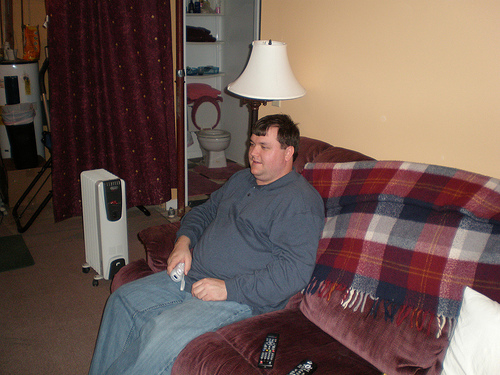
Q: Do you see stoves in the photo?
A: No, there are no stoves.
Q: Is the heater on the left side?
A: Yes, the heater is on the left of the image.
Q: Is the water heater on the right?
A: No, the heater is on the left of the image.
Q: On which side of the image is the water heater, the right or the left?
A: The heater is on the left of the image.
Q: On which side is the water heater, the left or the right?
A: The heater is on the left of the image.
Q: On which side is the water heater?
A: The heater is on the left of the image.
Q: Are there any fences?
A: No, there are no fences.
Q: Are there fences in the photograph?
A: No, there are no fences.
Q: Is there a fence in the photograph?
A: No, there are no fences.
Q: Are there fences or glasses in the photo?
A: No, there are no fences or glasses.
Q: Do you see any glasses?
A: No, there are no glasses.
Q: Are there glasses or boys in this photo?
A: No, there are no glasses or boys.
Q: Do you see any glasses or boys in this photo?
A: No, there are no glasses or boys.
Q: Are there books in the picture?
A: No, there are no books.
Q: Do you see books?
A: No, there are no books.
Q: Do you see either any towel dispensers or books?
A: No, there are no books or towel dispensers.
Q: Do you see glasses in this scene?
A: No, there are no glasses.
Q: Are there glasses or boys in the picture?
A: No, there are no glasses or boys.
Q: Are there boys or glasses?
A: No, there are no glasses or boys.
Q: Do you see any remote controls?
A: Yes, there is a remote control.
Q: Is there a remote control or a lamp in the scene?
A: Yes, there is a remote control.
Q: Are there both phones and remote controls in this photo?
A: No, there is a remote control but no phones.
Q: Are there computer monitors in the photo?
A: No, there are no computer monitors.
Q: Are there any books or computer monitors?
A: No, there are no computer monitors or books.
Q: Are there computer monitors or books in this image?
A: No, there are no computer monitors or books.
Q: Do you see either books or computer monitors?
A: No, there are no computer monitors or books.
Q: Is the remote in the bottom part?
A: Yes, the remote is in the bottom of the image.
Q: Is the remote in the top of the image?
A: No, the remote is in the bottom of the image.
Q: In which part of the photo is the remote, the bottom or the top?
A: The remote is in the bottom of the image.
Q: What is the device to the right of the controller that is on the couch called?
A: The device is a remote control.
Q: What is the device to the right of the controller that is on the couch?
A: The device is a remote control.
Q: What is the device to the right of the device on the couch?
A: The device is a remote control.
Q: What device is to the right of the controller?
A: The device is a remote control.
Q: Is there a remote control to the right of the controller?
A: Yes, there is a remote control to the right of the controller.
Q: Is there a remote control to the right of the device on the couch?
A: Yes, there is a remote control to the right of the controller.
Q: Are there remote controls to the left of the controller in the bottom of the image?
A: No, the remote control is to the right of the controller.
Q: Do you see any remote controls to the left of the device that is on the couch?
A: No, the remote control is to the right of the controller.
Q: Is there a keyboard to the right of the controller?
A: No, there is a remote control to the right of the controller.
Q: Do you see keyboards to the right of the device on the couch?
A: No, there is a remote control to the right of the controller.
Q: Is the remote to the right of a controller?
A: Yes, the remote is to the right of a controller.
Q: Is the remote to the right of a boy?
A: No, the remote is to the right of a controller.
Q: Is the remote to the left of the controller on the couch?
A: No, the remote is to the right of the controller.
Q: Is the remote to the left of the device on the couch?
A: No, the remote is to the right of the controller.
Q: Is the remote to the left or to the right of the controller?
A: The remote is to the right of the controller.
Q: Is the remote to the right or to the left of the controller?
A: The remote is to the right of the controller.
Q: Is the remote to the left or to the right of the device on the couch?
A: The remote is to the right of the controller.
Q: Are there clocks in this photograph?
A: No, there are no clocks.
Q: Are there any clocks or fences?
A: No, there are no clocks or fences.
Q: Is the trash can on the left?
A: Yes, the trash can is on the left of the image.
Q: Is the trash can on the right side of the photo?
A: No, the trash can is on the left of the image.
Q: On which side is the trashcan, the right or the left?
A: The trashcan is on the left of the image.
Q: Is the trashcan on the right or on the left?
A: The trashcan is on the left of the image.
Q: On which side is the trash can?
A: The trash can is on the left of the image.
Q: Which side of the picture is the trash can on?
A: The trash can is on the left of the image.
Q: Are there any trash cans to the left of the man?
A: Yes, there is a trash can to the left of the man.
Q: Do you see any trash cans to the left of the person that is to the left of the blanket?
A: Yes, there is a trash can to the left of the man.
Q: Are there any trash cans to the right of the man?
A: No, the trash can is to the left of the man.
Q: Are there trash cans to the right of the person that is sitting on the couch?
A: No, the trash can is to the left of the man.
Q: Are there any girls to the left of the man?
A: No, there is a trash can to the left of the man.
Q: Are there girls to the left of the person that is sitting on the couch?
A: No, there is a trash can to the left of the man.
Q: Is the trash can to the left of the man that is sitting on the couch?
A: Yes, the trash can is to the left of the man.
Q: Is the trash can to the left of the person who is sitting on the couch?
A: Yes, the trash can is to the left of the man.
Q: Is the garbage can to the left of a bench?
A: No, the garbage can is to the left of the man.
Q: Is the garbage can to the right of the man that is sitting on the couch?
A: No, the garbage can is to the left of the man.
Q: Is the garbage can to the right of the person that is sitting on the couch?
A: No, the garbage can is to the left of the man.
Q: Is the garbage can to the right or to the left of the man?
A: The garbage can is to the left of the man.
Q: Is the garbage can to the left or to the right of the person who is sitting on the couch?
A: The garbage can is to the left of the man.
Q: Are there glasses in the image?
A: No, there are no glasses.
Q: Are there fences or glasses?
A: No, there are no glasses or fences.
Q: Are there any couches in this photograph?
A: Yes, there is a couch.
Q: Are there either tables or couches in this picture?
A: Yes, there is a couch.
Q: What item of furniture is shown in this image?
A: The piece of furniture is a couch.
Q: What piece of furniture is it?
A: The piece of furniture is a couch.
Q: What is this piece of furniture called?
A: This is a couch.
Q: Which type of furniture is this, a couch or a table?
A: This is a couch.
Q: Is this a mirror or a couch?
A: This is a couch.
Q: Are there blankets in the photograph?
A: Yes, there is a blanket.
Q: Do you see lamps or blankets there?
A: Yes, there is a blanket.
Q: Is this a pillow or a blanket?
A: This is a blanket.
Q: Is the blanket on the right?
A: Yes, the blanket is on the right of the image.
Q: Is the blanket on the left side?
A: No, the blanket is on the right of the image.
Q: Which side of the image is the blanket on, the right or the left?
A: The blanket is on the right of the image.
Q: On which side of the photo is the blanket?
A: The blanket is on the right of the image.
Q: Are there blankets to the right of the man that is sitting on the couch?
A: Yes, there is a blanket to the right of the man.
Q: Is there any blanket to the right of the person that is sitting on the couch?
A: Yes, there is a blanket to the right of the man.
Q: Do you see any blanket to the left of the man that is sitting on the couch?
A: No, the blanket is to the right of the man.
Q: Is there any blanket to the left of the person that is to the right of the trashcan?
A: No, the blanket is to the right of the man.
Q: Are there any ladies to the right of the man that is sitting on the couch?
A: No, there is a blanket to the right of the man.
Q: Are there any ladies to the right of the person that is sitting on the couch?
A: No, there is a blanket to the right of the man.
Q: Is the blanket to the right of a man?
A: Yes, the blanket is to the right of a man.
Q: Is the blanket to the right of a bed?
A: No, the blanket is to the right of a man.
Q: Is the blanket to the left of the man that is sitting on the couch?
A: No, the blanket is to the right of the man.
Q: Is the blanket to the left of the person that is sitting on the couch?
A: No, the blanket is to the right of the man.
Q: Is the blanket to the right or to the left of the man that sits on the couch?
A: The blanket is to the right of the man.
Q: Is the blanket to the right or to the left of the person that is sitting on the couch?
A: The blanket is to the right of the man.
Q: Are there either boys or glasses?
A: No, there are no glasses or boys.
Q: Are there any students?
A: No, there are no students.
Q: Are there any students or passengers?
A: No, there are no students or passengers.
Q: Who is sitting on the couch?
A: The man is sitting on the couch.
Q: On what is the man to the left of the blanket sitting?
A: The man is sitting on the couch.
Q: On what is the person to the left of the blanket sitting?
A: The man is sitting on the couch.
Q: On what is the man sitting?
A: The man is sitting on the couch.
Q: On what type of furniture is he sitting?
A: The man is sitting on the couch.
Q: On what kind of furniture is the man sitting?
A: The man is sitting on the couch.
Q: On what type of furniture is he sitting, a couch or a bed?
A: The man is sitting on a couch.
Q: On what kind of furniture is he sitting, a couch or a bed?
A: The man is sitting on a couch.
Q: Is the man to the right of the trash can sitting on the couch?
A: Yes, the man is sitting on the couch.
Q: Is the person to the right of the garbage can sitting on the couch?
A: Yes, the man is sitting on the couch.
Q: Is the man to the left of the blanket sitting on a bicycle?
A: No, the man is sitting on the couch.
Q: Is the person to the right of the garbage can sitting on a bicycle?
A: No, the man is sitting on the couch.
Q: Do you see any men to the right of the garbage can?
A: Yes, there is a man to the right of the garbage can.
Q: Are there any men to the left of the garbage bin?
A: No, the man is to the right of the garbage bin.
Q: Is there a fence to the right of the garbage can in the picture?
A: No, there is a man to the right of the garbage can.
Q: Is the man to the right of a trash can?
A: Yes, the man is to the right of a trash can.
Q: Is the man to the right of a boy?
A: No, the man is to the right of a trash can.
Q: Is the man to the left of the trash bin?
A: No, the man is to the right of the trash bin.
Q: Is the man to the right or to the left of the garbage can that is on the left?
A: The man is to the right of the garbage can.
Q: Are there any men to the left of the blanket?
A: Yes, there is a man to the left of the blanket.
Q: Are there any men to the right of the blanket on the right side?
A: No, the man is to the left of the blanket.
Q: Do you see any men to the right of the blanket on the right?
A: No, the man is to the left of the blanket.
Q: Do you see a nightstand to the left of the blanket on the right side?
A: No, there is a man to the left of the blanket.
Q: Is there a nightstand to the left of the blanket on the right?
A: No, there is a man to the left of the blanket.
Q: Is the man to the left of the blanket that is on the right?
A: Yes, the man is to the left of the blanket.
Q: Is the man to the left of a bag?
A: No, the man is to the left of the blanket.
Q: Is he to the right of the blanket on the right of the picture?
A: No, the man is to the left of the blanket.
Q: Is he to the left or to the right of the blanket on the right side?
A: The man is to the left of the blanket.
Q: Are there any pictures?
A: No, there are no pictures.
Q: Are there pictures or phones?
A: No, there are no pictures or phones.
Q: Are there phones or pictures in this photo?
A: No, there are no pictures or phones.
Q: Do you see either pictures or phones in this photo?
A: No, there are no pictures or phones.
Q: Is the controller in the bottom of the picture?
A: Yes, the controller is in the bottom of the image.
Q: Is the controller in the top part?
A: No, the controller is in the bottom of the image.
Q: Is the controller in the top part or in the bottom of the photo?
A: The controller is in the bottom of the image.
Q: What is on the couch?
A: The controller is on the couch.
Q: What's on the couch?
A: The controller is on the couch.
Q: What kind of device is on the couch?
A: The device is a controller.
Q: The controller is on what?
A: The controller is on the couch.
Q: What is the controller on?
A: The controller is on the couch.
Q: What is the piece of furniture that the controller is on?
A: The piece of furniture is a couch.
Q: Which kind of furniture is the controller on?
A: The controller is on the couch.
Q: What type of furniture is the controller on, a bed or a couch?
A: The controller is on a couch.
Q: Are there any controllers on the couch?
A: Yes, there is a controller on the couch.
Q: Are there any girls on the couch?
A: No, there is a controller on the couch.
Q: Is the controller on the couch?
A: Yes, the controller is on the couch.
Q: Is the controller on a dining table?
A: No, the controller is on the couch.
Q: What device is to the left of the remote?
A: The device is a controller.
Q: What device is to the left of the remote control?
A: The device is a controller.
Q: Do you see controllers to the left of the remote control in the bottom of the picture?
A: Yes, there is a controller to the left of the remote.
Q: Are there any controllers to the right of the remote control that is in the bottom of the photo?
A: No, the controller is to the left of the remote.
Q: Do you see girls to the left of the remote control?
A: No, there is a controller to the left of the remote control.